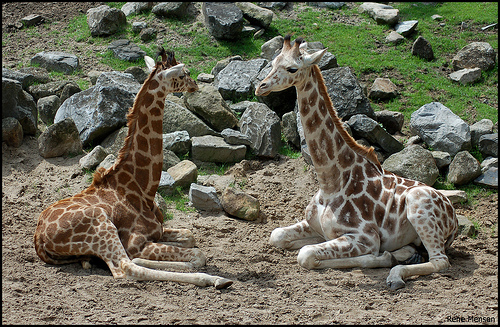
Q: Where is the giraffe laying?
A: On the ground.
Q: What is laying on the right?
A: Giraffe.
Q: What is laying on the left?
A: A giraffe.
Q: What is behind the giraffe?
A: Rocks.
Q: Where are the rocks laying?
A: On the grass.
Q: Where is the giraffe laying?
A: Sand.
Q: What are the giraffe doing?
A: Sitting on the sand.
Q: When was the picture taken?
A: Sunny day.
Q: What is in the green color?
A: Grass.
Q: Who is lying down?
A: Two giraffe.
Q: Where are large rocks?
A: On the ground.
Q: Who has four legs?
A: One giraffe.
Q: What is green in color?
A: Grass.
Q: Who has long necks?
A: The giraffe.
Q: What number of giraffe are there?
A: Two.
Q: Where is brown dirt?
A: On the ground.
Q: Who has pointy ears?
A: Two giraffe.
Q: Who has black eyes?
A: The giraffe.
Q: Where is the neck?
A: On giraffe.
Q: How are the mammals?
A: Facing each other.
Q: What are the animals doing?
A: Sitting.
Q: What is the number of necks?
A: Two.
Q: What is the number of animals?
A: Two.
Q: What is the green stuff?
A: Grass.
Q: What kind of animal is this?
A: Giraffe.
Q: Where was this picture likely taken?
A: Zoo.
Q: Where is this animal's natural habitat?
A: Africa.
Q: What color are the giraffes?
A: Orange and white.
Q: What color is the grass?
A: Green.